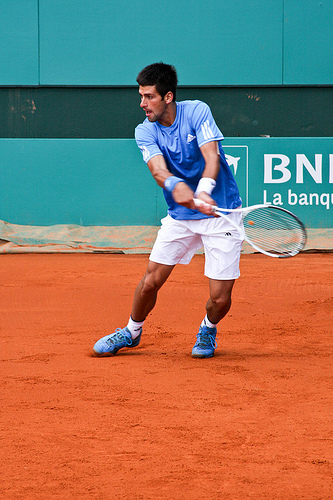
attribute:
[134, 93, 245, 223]
shirt — blue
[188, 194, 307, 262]
tennis racket — white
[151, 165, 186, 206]
wrist band — blue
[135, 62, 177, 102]
hair — black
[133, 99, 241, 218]
shirt — white, blue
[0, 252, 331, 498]
dirt — orange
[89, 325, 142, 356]
shoe — blue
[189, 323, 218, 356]
shoe — blue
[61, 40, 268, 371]
player — tennis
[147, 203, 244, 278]
shorts — white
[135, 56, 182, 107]
hair — black